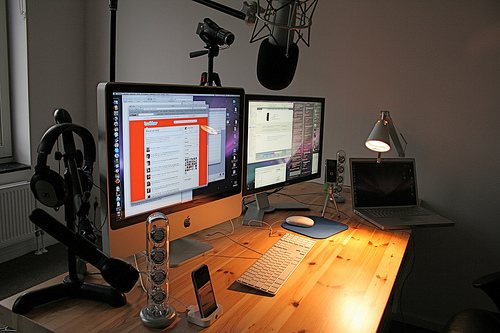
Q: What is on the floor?
A: Computer.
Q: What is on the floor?
A: Monitor.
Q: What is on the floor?
A: Monitor.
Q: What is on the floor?
A: Desk.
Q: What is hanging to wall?
A: Equipment.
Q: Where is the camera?
A: Behind the monitor, closest to the mousepad.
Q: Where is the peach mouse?
A: On a grey mouse pad.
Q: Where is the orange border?
A: Surrounding text, on a screen.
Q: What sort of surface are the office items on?
A: A wooden desk.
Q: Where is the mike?
A: Hanging above the monitors.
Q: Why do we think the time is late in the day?
A: Because there is little natural light coming from the uncurtained window.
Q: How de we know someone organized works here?
A: Because everything is very tidily arranged and clean. .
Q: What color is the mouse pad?
A: Blue.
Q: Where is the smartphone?
A: In the charger.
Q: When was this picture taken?
A: Daytime.